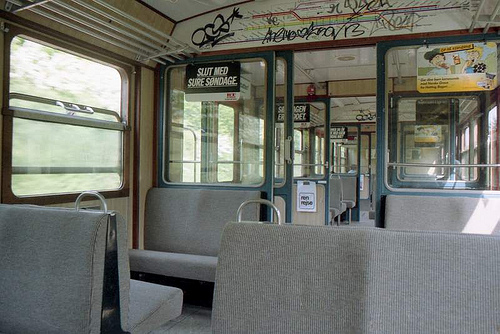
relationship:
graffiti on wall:
[188, 13, 250, 44] [140, 12, 487, 78]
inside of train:
[266, 47, 388, 286] [6, 5, 499, 333]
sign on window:
[187, 64, 239, 91] [12, 96, 126, 196]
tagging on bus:
[368, 21, 410, 42] [14, 10, 490, 320]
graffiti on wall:
[188, 13, 250, 44] [174, 0, 484, 50]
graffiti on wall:
[188, 13, 250, 44] [183, 0, 498, 47]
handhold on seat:
[234, 197, 281, 222] [203, 196, 499, 334]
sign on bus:
[184, 63, 240, 98] [14, 10, 490, 320]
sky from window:
[11, 46, 126, 146] [5, 21, 140, 204]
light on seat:
[449, 198, 483, 236] [203, 196, 499, 334]